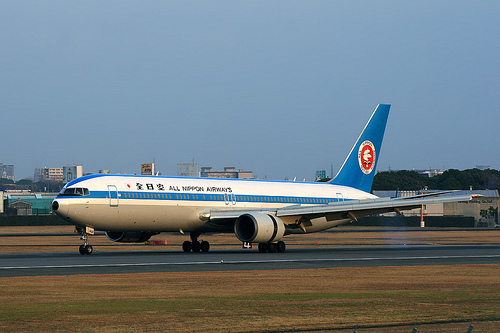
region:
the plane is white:
[37, 97, 498, 287]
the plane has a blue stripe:
[57, 185, 378, 212]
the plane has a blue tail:
[317, 97, 404, 194]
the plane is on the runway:
[7, 88, 499, 275]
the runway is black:
[5, 240, 497, 305]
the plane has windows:
[52, 184, 92, 203]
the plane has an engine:
[229, 206, 280, 244]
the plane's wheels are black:
[175, 239, 225, 250]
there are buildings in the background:
[5, 156, 92, 193]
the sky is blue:
[3, 0, 496, 187]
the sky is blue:
[155, 21, 353, 128]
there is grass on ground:
[68, 291, 478, 313]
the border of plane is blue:
[91, 189, 323, 204]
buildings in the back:
[32, 160, 83, 187]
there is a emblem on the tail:
[360, 143, 379, 180]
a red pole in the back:
[417, 198, 426, 238]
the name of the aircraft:
[138, 185, 235, 197]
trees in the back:
[448, 168, 498, 191]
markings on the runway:
[42, 248, 395, 270]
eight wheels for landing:
[79, 242, 294, 259]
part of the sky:
[355, 29, 421, 66]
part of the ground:
[262, 287, 300, 322]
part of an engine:
[243, 214, 269, 235]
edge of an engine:
[240, 205, 265, 242]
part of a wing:
[346, 196, 395, 216]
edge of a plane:
[151, 205, 188, 228]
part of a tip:
[38, 190, 58, 217]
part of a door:
[98, 171, 129, 211]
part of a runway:
[245, 250, 280, 268]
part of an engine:
[237, 222, 272, 250]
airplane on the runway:
[51, 99, 497, 271]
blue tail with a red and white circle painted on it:
[330, 91, 398, 193]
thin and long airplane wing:
[281, 183, 496, 213]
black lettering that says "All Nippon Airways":
[171, 181, 241, 193]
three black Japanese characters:
[134, 178, 166, 189]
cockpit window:
[58, 185, 93, 195]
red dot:
[124, 178, 134, 190]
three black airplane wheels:
[180, 237, 214, 253]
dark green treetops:
[374, 166, 492, 190]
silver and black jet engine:
[235, 210, 285, 241]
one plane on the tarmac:
[32, 160, 493, 234]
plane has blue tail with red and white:
[331, 74, 399, 265]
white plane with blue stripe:
[70, 154, 354, 269]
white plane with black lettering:
[32, 148, 404, 280]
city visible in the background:
[8, 131, 376, 251]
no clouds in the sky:
[1, 2, 481, 166]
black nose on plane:
[45, 182, 100, 230]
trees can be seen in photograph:
[345, 144, 489, 254]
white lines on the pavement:
[14, 234, 492, 274]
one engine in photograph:
[240, 202, 311, 264]